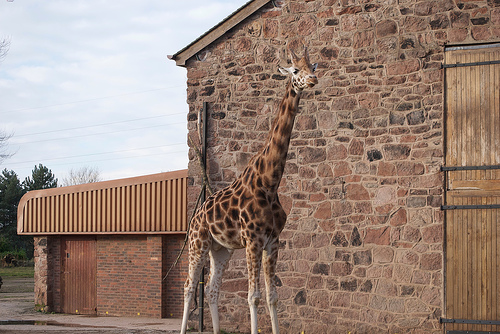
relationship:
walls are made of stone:
[169, 0, 500, 329] [167, 2, 500, 333]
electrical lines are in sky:
[2, 106, 187, 166] [2, 1, 249, 190]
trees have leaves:
[1, 117, 110, 267] [1, 164, 67, 266]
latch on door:
[440, 162, 499, 175] [440, 41, 499, 333]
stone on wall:
[167, 2, 500, 333] [169, 0, 500, 329]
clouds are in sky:
[2, 1, 244, 187] [2, 1, 249, 190]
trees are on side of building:
[1, 117, 110, 267] [13, 0, 500, 333]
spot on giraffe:
[289, 88, 298, 98] [161, 45, 329, 333]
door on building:
[440, 41, 499, 333] [13, 0, 500, 333]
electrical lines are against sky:
[2, 106, 187, 166] [2, 1, 249, 190]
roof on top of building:
[167, 0, 265, 67] [13, 0, 500, 333]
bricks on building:
[96, 237, 188, 316] [13, 0, 500, 333]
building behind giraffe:
[13, 0, 500, 333] [161, 45, 329, 333]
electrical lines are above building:
[2, 106, 187, 166] [13, 0, 500, 333]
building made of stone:
[13, 0, 500, 333] [167, 2, 500, 333]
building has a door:
[13, 0, 500, 333] [440, 41, 499, 333]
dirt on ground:
[1, 285, 38, 293] [2, 278, 184, 334]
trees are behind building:
[1, 117, 110, 267] [13, 0, 500, 333]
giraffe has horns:
[161, 45, 329, 333] [286, 45, 314, 63]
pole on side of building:
[196, 100, 211, 333] [13, 0, 500, 333]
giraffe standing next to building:
[161, 45, 329, 333] [13, 0, 500, 333]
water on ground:
[130, 319, 170, 328] [2, 278, 184, 334]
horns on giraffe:
[286, 45, 314, 63] [161, 45, 329, 333]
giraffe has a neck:
[161, 45, 329, 333] [259, 86, 307, 185]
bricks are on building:
[96, 237, 188, 316] [13, 0, 500, 333]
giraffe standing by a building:
[161, 45, 329, 333] [13, 0, 500, 333]